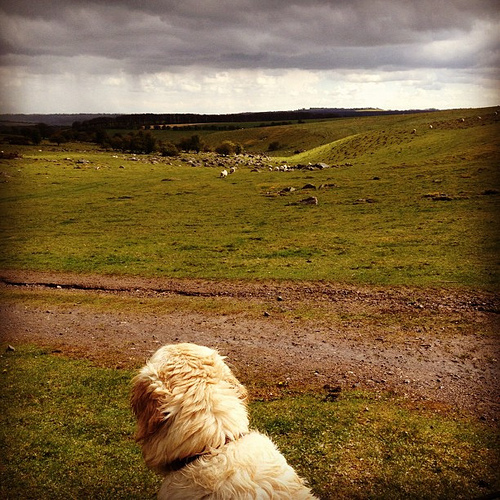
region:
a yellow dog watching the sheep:
[117, 353, 288, 498]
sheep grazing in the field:
[102, 148, 323, 195]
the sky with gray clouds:
[15, 3, 495, 113]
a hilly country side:
[7, 88, 498, 363]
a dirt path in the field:
[6, 272, 498, 395]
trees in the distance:
[37, 124, 176, 173]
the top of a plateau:
[273, 97, 420, 129]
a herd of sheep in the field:
[100, 135, 330, 208]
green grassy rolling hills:
[22, 126, 494, 312]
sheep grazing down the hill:
[381, 99, 499, 146]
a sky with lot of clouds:
[82, 25, 470, 88]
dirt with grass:
[271, 331, 466, 456]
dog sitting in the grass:
[109, 338, 265, 495]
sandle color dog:
[135, 359, 297, 495]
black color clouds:
[55, 10, 432, 66]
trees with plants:
[32, 120, 186, 159]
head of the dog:
[123, 338, 247, 446]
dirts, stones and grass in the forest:
[26, 108, 443, 312]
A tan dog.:
[129, 341, 318, 498]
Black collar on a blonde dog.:
[158, 429, 253, 472]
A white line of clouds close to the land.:
[4, 61, 499, 110]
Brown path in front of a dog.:
[1, 299, 498, 388]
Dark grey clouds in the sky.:
[1, 0, 498, 58]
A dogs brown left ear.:
[131, 370, 172, 442]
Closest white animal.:
[219, 166, 228, 178]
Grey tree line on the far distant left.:
[1, 111, 96, 126]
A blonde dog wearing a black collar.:
[130, 342, 322, 498]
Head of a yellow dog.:
[128, 342, 250, 467]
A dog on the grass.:
[128, 340, 318, 498]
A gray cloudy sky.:
[0, 25, 498, 114]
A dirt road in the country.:
[0, 267, 499, 419]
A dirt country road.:
[3, 266, 498, 416]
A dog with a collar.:
[131, 342, 320, 499]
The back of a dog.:
[130, 341, 317, 498]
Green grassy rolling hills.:
[3, 105, 499, 289]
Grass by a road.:
[2, 342, 498, 499]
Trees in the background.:
[3, 106, 439, 166]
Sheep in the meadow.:
[217, 163, 237, 178]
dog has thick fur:
[124, 297, 319, 487]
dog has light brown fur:
[124, 366, 308, 493]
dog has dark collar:
[171, 386, 269, 490]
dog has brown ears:
[85, 300, 308, 499]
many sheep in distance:
[103, 149, 343, 234]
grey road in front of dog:
[1, 273, 457, 428]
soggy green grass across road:
[40, 156, 486, 271]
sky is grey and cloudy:
[6, 1, 466, 108]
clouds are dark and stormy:
[29, 1, 447, 83]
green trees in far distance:
[91, 103, 366, 139]